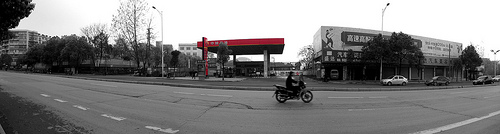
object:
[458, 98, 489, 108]
no objects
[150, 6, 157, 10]
street light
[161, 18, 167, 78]
pole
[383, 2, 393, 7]
street light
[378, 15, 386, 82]
pole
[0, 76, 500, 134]
street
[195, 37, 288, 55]
canopy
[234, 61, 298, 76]
building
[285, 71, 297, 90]
person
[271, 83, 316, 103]
motorcycle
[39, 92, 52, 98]
line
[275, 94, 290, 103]
wheel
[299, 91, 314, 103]
wheel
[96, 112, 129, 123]
line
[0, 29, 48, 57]
building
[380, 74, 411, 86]
car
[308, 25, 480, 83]
building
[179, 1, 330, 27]
sky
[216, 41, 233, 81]
tree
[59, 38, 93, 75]
tree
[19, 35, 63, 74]
tree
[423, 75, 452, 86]
car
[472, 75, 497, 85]
car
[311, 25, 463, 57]
sign